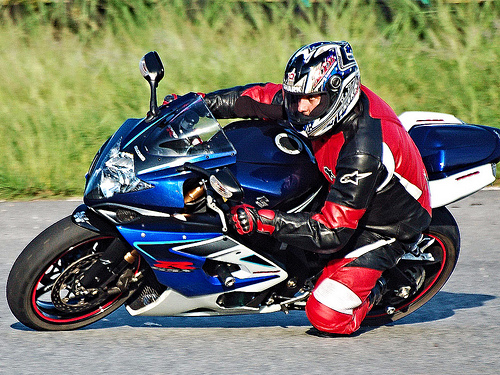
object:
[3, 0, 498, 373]
ground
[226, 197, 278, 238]
glove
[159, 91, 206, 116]
glove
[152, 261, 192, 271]
logo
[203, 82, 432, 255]
jacket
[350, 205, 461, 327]
wheel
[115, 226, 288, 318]
trim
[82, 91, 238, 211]
trim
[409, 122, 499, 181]
trim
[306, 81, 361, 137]
silver plate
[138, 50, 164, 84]
mirror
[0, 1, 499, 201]
grass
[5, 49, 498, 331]
motorbike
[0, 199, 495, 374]
road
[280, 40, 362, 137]
helmet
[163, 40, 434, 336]
man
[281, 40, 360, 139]
head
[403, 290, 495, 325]
shadow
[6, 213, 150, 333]
wheel